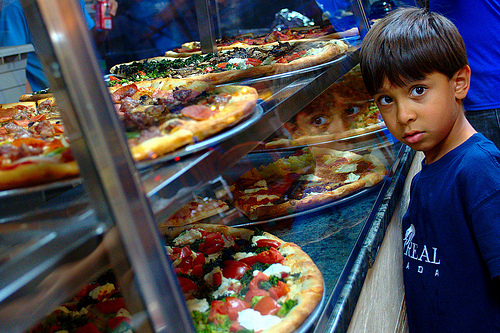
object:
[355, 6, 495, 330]
boy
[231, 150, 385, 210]
pizza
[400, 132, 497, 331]
shirt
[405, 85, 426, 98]
eyes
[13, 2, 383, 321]
display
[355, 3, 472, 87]
hair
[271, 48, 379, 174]
reflection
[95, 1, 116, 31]
soda can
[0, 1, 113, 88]
person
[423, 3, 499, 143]
person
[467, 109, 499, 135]
jeans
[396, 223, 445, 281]
logo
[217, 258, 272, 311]
tomatoes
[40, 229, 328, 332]
pizza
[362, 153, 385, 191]
crust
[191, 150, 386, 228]
tray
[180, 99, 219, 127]
pepperoni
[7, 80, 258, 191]
pizza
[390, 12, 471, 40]
light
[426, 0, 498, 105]
shirt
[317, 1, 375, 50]
reflection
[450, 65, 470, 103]
ear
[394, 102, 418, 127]
nose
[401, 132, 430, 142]
lips